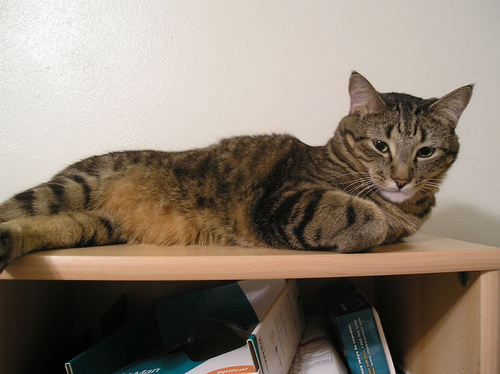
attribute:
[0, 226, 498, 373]
shelf — wooden, brown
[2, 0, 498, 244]
wall — white, clean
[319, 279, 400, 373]
box — small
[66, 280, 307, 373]
box — small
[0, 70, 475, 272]
cat — grey, large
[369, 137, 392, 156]
eye — golden, open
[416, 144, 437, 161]
eye — golden, open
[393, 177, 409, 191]
nose — pink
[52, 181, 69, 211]
stripes — dark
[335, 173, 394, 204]
whiskers — white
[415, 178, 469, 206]
whiskers — white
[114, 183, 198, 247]
tummy — tan